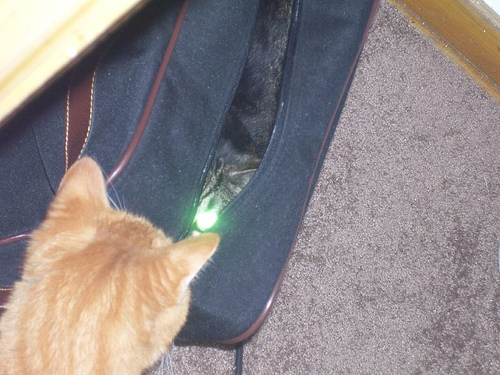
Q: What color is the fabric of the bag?
A: Dark blue.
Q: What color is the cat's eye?
A: Green.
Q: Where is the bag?
A: On the ground.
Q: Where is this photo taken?
A: Inside a room of a house.